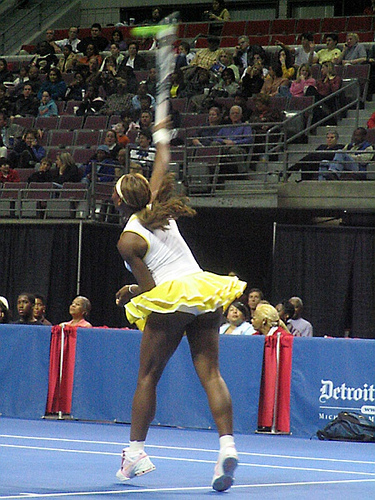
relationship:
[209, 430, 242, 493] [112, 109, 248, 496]
shoe of player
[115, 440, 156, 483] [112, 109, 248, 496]
shoe of player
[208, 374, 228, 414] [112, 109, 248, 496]
calf of player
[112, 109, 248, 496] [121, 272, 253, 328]
player wearing skirt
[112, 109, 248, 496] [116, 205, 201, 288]
player wearing top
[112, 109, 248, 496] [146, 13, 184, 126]
player holding racquet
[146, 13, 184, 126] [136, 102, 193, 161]
racquet in right hand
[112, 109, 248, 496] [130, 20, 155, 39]
player jumping up to ball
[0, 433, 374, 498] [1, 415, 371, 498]
lines on floor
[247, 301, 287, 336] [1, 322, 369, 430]
spectator in box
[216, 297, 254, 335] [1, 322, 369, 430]
spectator in box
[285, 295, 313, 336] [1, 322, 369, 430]
spectator in box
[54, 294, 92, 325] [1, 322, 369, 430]
spectator in box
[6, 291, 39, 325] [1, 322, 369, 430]
spectator in box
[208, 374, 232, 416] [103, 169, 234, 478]
calf on player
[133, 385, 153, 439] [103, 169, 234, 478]
calves on player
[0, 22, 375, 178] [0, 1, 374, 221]
people seated high up in bleachers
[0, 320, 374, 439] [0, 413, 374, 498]
box separating tennis court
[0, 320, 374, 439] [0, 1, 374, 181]
box separating people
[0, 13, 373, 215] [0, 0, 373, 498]
seats at stadium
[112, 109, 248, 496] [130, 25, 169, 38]
player serving ball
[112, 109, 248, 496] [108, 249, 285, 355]
player wearing skirt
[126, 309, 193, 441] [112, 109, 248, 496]
leg of player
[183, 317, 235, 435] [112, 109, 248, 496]
leg of player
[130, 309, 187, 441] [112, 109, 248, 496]
leg of player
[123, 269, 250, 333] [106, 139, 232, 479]
skirt of woman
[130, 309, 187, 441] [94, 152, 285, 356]
leg of woman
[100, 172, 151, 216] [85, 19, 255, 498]
head of woman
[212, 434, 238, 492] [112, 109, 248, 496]
shoe of player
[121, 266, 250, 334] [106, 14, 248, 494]
skirt on woman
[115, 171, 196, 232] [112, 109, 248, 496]
hair of player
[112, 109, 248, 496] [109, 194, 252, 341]
player in outfit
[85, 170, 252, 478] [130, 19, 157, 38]
player reaching high for ball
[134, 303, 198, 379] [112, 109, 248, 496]
thigh on player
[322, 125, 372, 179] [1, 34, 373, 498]
audience member watching tennis match